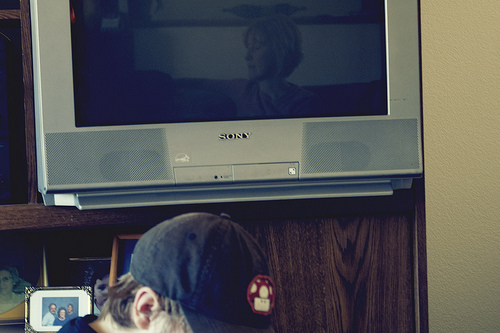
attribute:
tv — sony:
[31, 9, 437, 215]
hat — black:
[100, 215, 281, 329]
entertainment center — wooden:
[144, 204, 431, 324]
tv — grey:
[31, 2, 431, 195]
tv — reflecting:
[47, 16, 422, 210]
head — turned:
[230, 21, 343, 146]